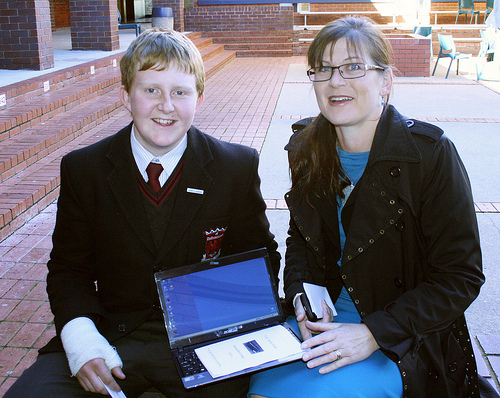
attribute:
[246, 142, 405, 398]
dress — blue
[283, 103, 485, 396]
jacket — black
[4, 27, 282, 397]
boy — smiling, young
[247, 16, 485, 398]
woman — smiling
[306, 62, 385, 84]
glasses — prescription, dark rimmed, gold trimmed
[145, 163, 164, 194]
tie — red, maroon, burgundy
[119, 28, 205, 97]
hair — short, blonde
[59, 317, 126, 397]
hand — injured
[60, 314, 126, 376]
cast — white, gauze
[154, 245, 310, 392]
laptop — open, black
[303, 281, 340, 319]
envelope — white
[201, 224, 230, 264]
insignia — maroon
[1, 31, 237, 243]
steps — brick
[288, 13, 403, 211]
hair — pulled back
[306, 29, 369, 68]
bangs — side swept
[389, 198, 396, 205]
eyelet — metal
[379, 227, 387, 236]
eyelet — metal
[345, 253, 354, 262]
eyelet — metal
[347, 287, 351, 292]
eyelet — metal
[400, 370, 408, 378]
eyelet — metal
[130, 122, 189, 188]
shirt — dressy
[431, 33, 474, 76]
patio chair — green, resin, turquoise blue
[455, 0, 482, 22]
patio chair — green, resin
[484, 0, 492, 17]
patio chair — green, resin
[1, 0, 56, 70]
column — brick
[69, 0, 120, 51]
column — brick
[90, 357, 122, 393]
finger — injured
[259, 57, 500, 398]
patio — gray, cement, divided